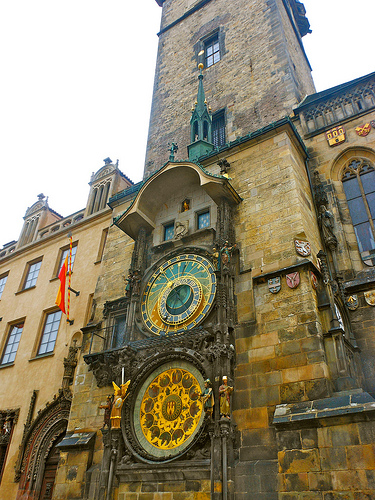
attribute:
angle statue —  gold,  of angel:
[108, 377, 133, 429]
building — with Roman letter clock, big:
[0, 2, 372, 499]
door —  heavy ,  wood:
[82, 442, 101, 500]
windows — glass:
[7, 245, 102, 352]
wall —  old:
[1, 74, 373, 498]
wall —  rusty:
[251, 331, 316, 392]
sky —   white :
[34, 22, 126, 115]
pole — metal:
[66, 233, 78, 324]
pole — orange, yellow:
[65, 233, 71, 329]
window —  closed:
[46, 315, 61, 337]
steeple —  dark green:
[176, 47, 222, 157]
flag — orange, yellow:
[52, 237, 76, 316]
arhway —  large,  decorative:
[20, 395, 69, 492]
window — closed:
[19, 258, 41, 291]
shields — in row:
[262, 273, 308, 293]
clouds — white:
[52, 66, 134, 148]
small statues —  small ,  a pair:
[197, 374, 233, 422]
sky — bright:
[32, 18, 182, 120]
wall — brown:
[2, 212, 116, 497]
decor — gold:
[100, 356, 238, 474]